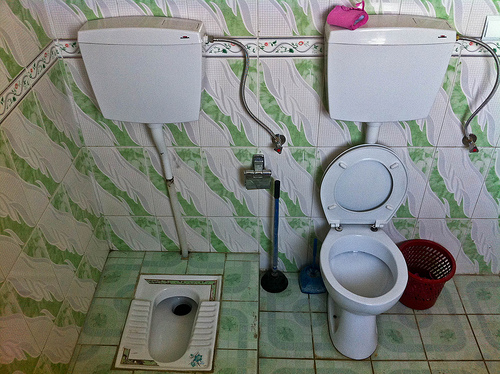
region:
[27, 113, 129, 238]
green patterned tile with white grout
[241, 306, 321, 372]
filthy grout in between bathroom floor tiles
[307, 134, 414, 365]
toilet with lid and seat open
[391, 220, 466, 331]
red plastic waste basket with holes in it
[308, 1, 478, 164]
toilet tank mounted to the wall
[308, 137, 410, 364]
white porcelain toilet mounted to floor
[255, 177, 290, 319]
black plastic plunger with blue handle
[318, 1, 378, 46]
pink item sitting on top of toilet tank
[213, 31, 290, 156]
silver bent pipe coming out of wall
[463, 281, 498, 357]
blue and green design in flooring tiles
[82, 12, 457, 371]
Two bathroom fixtures side by side.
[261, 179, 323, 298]
Toilet plunger and cleaning brush.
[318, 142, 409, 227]
Toilet lid is up.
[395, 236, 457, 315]
Red basket has holes in the sides.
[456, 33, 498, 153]
Water pipe to feed fixture.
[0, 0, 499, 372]
Green and white tile on wall.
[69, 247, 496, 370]
Tiles are on the floor.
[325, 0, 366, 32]
A pink purse is setting on the surface.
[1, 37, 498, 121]
Tile border has some pink flowers.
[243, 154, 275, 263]
Silver object has a hinge.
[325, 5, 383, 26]
The pink roll on top of the toilet.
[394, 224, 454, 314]
The red basket on the right.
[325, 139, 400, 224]
The toilet seat and lid.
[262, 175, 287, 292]
The toilet plunger to the left of the toilet.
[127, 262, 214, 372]
The urinal on the ground.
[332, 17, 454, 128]
The water tank of the toilet.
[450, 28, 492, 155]
The pipe coming out of the water tank of the toilet.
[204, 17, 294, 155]
The pipe coming out of the water tank to the urinal.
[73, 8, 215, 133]
The water tank of the urinal.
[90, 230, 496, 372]
The designed tiles on the floor.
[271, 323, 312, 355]
part of a floor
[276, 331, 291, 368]
part of a floor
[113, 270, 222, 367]
a white porcelain floor toilet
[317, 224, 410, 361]
a white porcelain toilet basin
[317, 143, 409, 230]
a white plastic toilet seat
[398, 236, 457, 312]
a red trash can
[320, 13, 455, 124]
a white porcelain toilet tank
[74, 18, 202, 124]
a white porcelain toilet tank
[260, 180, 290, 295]
a toilet bowl plunger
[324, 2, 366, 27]
a pink wallet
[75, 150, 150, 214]
a white and green wall tile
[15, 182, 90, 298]
a white and green wall tile